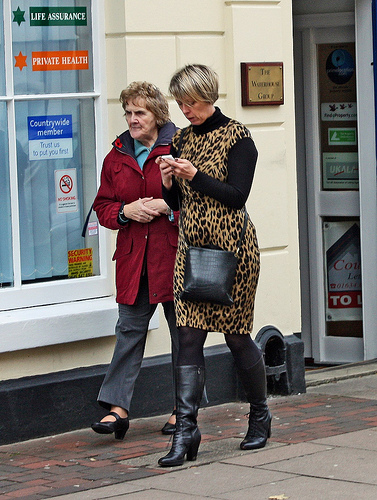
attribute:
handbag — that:
[165, 203, 262, 319]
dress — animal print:
[184, 145, 226, 308]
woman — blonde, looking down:
[162, 66, 269, 443]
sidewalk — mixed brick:
[284, 408, 331, 479]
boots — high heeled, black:
[172, 358, 299, 446]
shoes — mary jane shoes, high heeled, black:
[54, 402, 204, 433]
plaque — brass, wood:
[243, 63, 303, 112]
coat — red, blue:
[93, 121, 174, 272]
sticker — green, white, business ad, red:
[16, 5, 96, 27]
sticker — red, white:
[19, 45, 87, 72]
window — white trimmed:
[10, 46, 95, 278]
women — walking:
[96, 88, 269, 385]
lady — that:
[101, 86, 178, 411]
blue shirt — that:
[130, 140, 151, 165]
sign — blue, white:
[27, 119, 78, 149]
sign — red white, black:
[53, 172, 76, 204]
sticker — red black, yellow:
[57, 249, 99, 280]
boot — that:
[235, 371, 265, 444]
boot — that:
[168, 367, 203, 455]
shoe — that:
[82, 414, 143, 441]